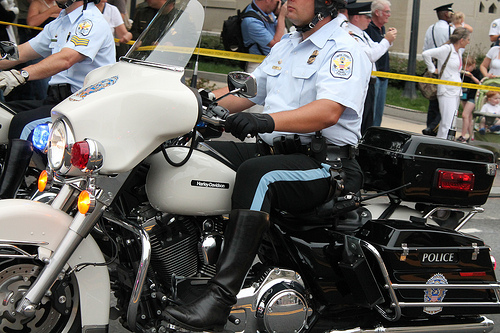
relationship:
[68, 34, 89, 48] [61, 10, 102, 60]
rank on mans sholuder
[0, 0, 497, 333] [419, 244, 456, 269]
bike for police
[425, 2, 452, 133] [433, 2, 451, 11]
police officer wearing cap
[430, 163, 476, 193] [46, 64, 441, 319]
light on motorcycle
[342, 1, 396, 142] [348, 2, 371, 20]
man wearing hat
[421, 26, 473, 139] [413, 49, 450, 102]
woman carrying purse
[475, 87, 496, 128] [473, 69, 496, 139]
kid in stroller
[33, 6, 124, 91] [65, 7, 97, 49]
shirt has emblem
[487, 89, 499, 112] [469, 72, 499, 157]
toddler in stroller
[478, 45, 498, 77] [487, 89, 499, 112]
woman has toddler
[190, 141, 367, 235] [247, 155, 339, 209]
pants with stripe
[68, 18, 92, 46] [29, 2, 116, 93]
patch on shirt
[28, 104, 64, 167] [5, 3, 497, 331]
light on motorcycle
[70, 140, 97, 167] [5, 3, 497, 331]
light on motorcycle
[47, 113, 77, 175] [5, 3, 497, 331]
light on motorcycle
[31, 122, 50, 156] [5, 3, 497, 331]
light on motorcycle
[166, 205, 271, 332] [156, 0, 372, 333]
boot on man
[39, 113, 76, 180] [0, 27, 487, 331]
light on front of bike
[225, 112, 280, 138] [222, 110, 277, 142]
glove on hand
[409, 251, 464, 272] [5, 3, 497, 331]
word on motorcycle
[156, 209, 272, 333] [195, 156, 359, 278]
boot on leg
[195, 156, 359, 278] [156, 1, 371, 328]
leg of man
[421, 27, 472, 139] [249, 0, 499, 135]
woman in background